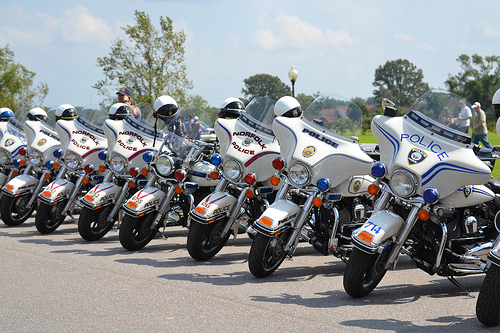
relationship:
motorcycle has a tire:
[249, 92, 382, 277] [344, 245, 390, 295]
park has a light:
[0, 9, 497, 182] [289, 67, 298, 82]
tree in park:
[374, 58, 429, 116] [0, 9, 497, 182]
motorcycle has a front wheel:
[249, 92, 382, 277] [250, 230, 292, 277]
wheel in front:
[188, 217, 230, 259] [189, 117, 283, 262]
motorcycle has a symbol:
[249, 92, 382, 277] [302, 146, 314, 159]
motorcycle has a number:
[249, 92, 382, 277] [365, 220, 382, 235]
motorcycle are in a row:
[249, 92, 382, 277] [1, 94, 499, 327]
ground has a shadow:
[0, 210, 498, 333] [160, 257, 421, 286]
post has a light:
[293, 79, 296, 96] [366, 182, 380, 198]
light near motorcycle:
[366, 182, 380, 198] [249, 92, 382, 277]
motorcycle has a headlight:
[249, 92, 382, 277] [391, 170, 418, 198]